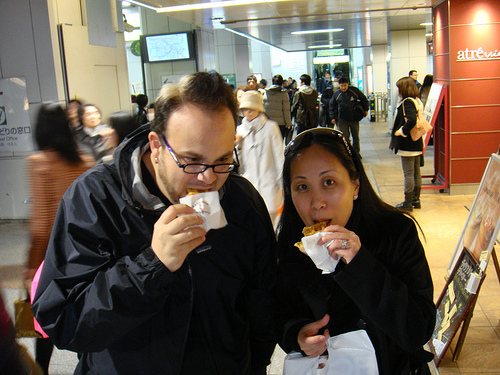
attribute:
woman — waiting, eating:
[276, 112, 432, 329]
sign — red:
[438, 26, 498, 86]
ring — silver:
[338, 235, 354, 249]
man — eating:
[97, 58, 266, 297]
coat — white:
[232, 112, 278, 195]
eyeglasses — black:
[151, 132, 251, 180]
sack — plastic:
[343, 332, 380, 372]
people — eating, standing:
[91, 98, 425, 367]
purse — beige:
[401, 108, 436, 157]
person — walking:
[325, 67, 371, 139]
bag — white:
[317, 327, 376, 374]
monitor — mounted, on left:
[135, 30, 213, 65]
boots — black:
[396, 178, 427, 211]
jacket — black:
[278, 201, 443, 349]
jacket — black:
[26, 154, 193, 277]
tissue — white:
[304, 237, 351, 268]